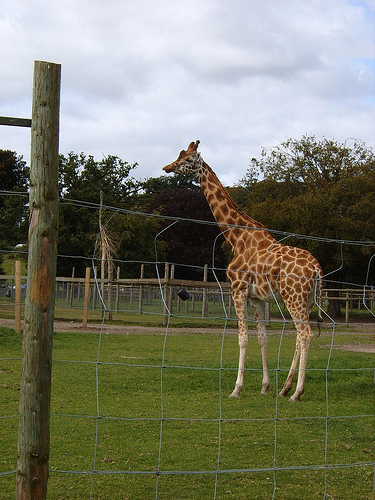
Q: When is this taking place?
A: Daytime.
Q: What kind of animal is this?
A: Giraffe.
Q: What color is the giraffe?
A: Brown and tan.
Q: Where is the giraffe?
A: Fenced enclosure.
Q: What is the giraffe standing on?
A: Grass.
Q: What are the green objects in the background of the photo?
A: Trees.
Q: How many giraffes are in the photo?
A: One.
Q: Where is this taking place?
A: The zoo.